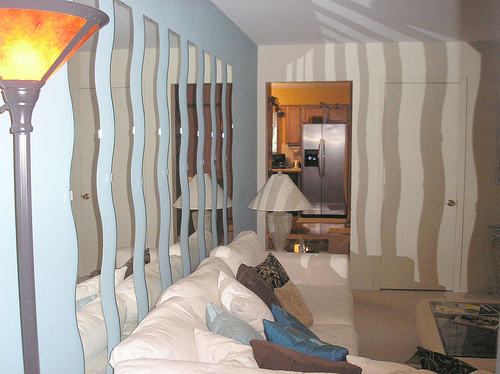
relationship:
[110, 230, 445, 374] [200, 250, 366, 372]
couch has pillows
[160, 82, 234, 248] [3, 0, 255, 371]
mirror on wall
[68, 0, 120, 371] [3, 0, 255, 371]
mirror on wall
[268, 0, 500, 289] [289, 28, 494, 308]
stripe on wall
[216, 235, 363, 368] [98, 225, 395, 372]
pillows on couch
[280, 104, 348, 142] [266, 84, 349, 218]
cabinets on wall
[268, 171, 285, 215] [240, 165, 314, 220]
stripe on lampshade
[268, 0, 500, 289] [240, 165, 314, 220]
stripe on lampshade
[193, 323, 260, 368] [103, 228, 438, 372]
pillow in corner couch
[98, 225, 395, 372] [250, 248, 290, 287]
couch with pillow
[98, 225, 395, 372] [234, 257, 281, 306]
couch with pillow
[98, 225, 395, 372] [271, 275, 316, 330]
couch with pillow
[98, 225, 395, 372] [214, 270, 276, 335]
couch with pillow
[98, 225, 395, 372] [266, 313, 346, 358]
couch with pillow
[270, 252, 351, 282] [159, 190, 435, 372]
arm of couch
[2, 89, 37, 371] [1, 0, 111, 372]
pole for floor lamp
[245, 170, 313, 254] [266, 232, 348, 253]
lamp on end table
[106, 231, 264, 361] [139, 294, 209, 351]
back section of couch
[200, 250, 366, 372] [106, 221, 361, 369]
pillows on sofa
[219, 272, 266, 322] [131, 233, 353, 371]
throw pillow on sofa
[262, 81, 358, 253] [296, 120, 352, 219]
mirror with reflection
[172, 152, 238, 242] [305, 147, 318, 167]
reflection with ice maker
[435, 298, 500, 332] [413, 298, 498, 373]
magazines on coffee table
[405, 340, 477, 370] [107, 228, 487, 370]
pillow laying on couch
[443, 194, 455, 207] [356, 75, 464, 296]
door knob on door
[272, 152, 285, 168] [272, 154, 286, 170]
coffee maker on coffee maker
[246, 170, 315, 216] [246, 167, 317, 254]
shade on lamp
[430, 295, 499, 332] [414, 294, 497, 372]
magazines on table